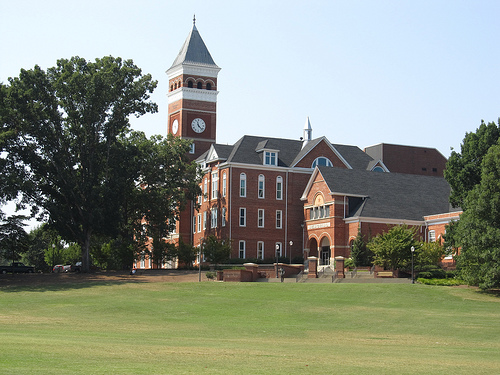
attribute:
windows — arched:
[231, 169, 286, 204]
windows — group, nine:
[235, 169, 288, 263]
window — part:
[245, 152, 305, 243]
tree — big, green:
[4, 51, 206, 268]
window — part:
[257, 172, 264, 199]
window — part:
[238, 170, 246, 196]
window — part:
[274, 208, 283, 229]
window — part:
[256, 208, 263, 227]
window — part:
[238, 240, 245, 259]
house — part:
[316, 165, 451, 218]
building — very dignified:
[89, 20, 474, 285]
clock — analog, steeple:
[188, 111, 211, 141]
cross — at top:
[187, 10, 198, 29]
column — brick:
[332, 256, 344, 282]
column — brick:
[306, 255, 320, 279]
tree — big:
[1, 54, 159, 272]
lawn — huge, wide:
[1, 265, 498, 371]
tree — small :
[346, 221, 448, 286]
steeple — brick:
[158, 14, 226, 142]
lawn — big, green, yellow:
[1, 290, 499, 374]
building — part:
[129, 18, 476, 275]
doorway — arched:
[317, 234, 333, 264]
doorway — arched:
[307, 234, 318, 258]